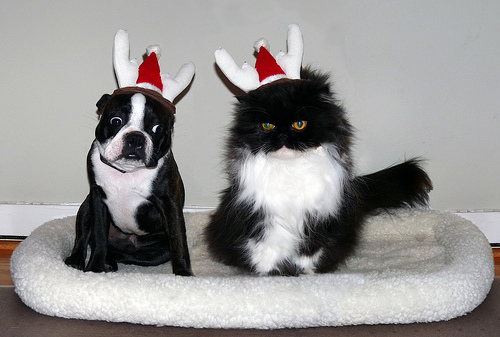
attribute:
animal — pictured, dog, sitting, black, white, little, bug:
[65, 93, 193, 276]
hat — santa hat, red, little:
[111, 29, 195, 113]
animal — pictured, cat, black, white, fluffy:
[199, 64, 432, 276]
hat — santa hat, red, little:
[215, 24, 311, 95]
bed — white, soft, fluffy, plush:
[9, 211, 494, 330]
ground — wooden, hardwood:
[0, 240, 498, 287]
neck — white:
[235, 145, 345, 167]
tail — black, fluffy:
[354, 158, 433, 215]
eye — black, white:
[108, 116, 121, 126]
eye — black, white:
[152, 124, 162, 134]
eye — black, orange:
[261, 121, 275, 130]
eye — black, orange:
[293, 121, 305, 130]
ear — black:
[96, 94, 109, 112]